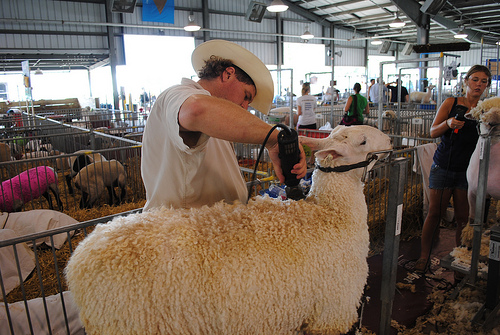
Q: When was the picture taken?
A: Daytime.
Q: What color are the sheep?
A: White.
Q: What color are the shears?
A: Black.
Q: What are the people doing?
A: Shearing.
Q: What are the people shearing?
A: Sheep.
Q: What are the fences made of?
A: Metal.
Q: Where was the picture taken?
A: An an agricultural event.